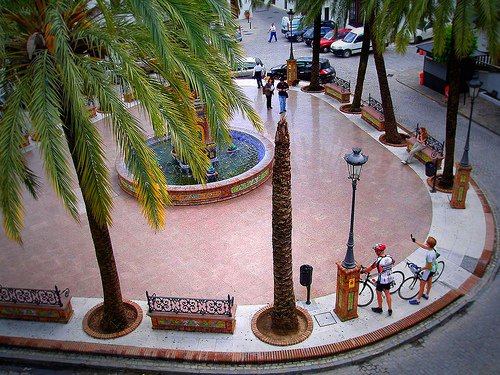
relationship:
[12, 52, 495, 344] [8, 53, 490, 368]
park in a city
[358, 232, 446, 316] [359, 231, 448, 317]
bicyclists at park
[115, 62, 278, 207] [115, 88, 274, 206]
fountain in park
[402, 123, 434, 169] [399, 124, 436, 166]
woman in park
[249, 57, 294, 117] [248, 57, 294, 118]
people around park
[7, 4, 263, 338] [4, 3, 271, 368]
palm tree in park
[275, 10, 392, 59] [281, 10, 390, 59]
cars outside park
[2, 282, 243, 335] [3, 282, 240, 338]
benches at side of the park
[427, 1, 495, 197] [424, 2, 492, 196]
that is a tree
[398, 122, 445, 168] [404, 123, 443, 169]
woman alone benches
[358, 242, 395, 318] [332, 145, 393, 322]
bicyclists next to lamp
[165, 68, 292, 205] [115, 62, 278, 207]
people next fountain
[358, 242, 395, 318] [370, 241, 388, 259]
bicyclists red helmet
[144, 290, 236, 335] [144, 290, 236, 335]
bench bench bench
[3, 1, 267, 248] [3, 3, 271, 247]
leaves on palm tree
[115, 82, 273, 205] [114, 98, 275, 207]
fountain near benches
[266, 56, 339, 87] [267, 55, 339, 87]
car on street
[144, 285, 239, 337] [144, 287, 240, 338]
bench near fountain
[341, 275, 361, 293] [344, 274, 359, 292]
sign near tree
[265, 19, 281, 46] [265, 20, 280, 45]
man crossing street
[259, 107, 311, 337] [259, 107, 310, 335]
no fronds palm tree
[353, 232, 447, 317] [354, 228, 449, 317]
two bikes with bicyclists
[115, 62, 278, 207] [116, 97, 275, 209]
fountain with water